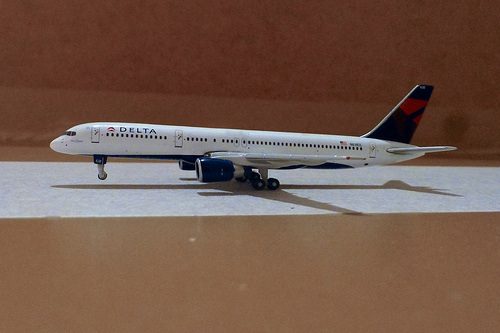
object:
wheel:
[96, 171, 108, 181]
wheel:
[263, 177, 281, 191]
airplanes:
[49, 84, 457, 192]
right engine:
[178, 156, 197, 171]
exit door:
[367, 141, 376, 159]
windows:
[63, 130, 76, 137]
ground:
[0, 141, 499, 332]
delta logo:
[106, 126, 158, 135]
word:
[118, 126, 126, 133]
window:
[198, 136, 203, 141]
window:
[190, 137, 194, 142]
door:
[172, 130, 185, 148]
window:
[111, 132, 114, 136]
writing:
[148, 127, 159, 134]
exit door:
[89, 125, 100, 144]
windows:
[343, 145, 349, 150]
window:
[299, 143, 304, 147]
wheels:
[251, 180, 266, 191]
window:
[104, 132, 109, 137]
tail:
[358, 83, 434, 144]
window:
[184, 136, 189, 140]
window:
[194, 137, 199, 142]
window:
[203, 137, 208, 143]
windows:
[357, 145, 362, 151]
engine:
[194, 156, 237, 186]